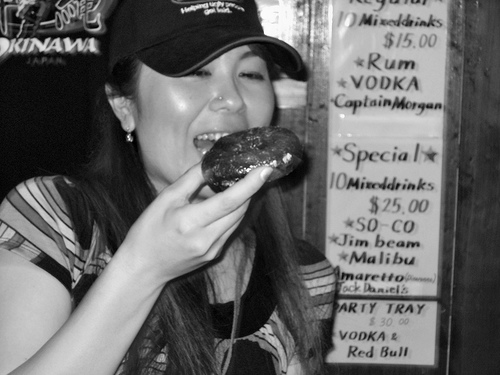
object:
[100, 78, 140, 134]
ear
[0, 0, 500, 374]
wall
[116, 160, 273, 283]
hand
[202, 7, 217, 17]
word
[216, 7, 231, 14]
word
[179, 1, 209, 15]
word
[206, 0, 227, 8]
word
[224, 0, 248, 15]
word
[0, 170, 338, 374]
shirt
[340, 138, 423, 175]
word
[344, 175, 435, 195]
word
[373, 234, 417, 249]
word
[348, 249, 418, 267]
word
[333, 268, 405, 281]
word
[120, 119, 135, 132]
lobe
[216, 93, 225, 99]
jewelry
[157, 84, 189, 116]
reflection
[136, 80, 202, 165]
cheek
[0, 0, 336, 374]
girl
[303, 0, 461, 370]
board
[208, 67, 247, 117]
nose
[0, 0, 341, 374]
woman eating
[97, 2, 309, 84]
baseball cap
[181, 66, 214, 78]
left eye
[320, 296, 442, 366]
bar sign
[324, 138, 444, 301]
drink sign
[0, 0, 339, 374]
woman with donut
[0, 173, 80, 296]
shirt sleeve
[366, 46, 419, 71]
handwritten words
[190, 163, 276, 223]
index finger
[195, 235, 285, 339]
shirt collar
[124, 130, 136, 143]
earring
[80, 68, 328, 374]
girl's hair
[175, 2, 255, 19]
white letters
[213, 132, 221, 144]
teeth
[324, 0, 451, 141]
sign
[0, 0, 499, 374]
black photograph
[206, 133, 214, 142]
woman's teeth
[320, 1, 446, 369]
list of drinks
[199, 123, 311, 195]
doughnut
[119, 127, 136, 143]
earring hangs down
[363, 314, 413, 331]
party tray price